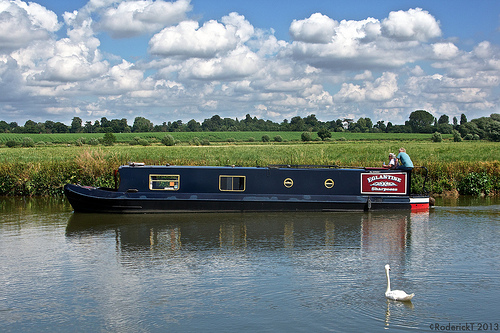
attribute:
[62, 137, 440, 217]
boat — blue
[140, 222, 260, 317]
water — calm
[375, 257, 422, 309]
duck — white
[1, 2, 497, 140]
sky — cloudy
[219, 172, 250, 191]
window — rectangular 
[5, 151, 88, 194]
grass water — growing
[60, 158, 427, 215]
boat — blue 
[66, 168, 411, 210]
boat — long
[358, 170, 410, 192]
sign — red, white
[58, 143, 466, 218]
boat — navy blue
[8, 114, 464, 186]
fields — green, grassy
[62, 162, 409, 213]
boat — blue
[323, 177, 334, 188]
window —  round 